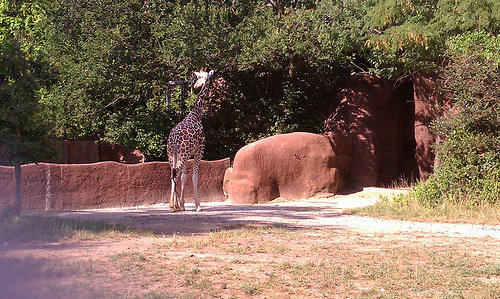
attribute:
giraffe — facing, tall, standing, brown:
[166, 68, 214, 212]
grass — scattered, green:
[5, 216, 495, 298]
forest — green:
[2, 4, 499, 213]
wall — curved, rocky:
[228, 130, 340, 203]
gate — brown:
[399, 82, 415, 182]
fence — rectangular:
[0, 157, 233, 215]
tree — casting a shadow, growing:
[0, 20, 63, 164]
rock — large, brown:
[230, 132, 355, 202]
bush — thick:
[3, 3, 325, 161]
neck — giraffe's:
[192, 79, 212, 120]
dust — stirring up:
[2, 168, 107, 289]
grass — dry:
[15, 240, 484, 296]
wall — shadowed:
[339, 70, 481, 185]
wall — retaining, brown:
[2, 157, 230, 217]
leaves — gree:
[5, 45, 39, 118]